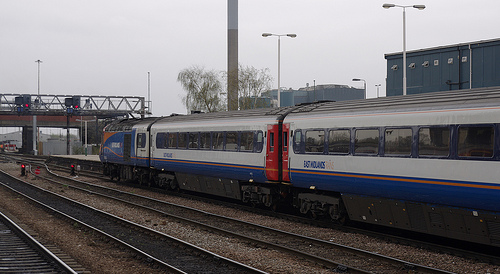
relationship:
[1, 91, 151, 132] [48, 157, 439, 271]
bridge above railroad tracks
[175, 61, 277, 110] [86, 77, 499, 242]
tree behind train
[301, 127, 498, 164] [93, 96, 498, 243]
windows on train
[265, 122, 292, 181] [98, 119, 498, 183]
doors on train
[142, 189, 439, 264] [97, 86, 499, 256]
railroad tracks under train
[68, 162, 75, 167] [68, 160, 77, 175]
light illuminated on post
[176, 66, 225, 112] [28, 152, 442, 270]
tree next to tracks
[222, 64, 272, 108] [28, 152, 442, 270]
tree next to tracks